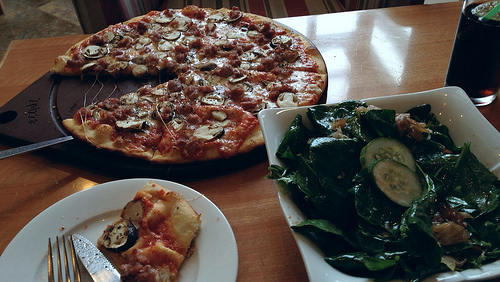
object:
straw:
[476, 1, 500, 23]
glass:
[442, 0, 499, 107]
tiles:
[1, 0, 36, 23]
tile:
[37, 0, 80, 25]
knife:
[69, 233, 124, 282]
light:
[278, 10, 413, 98]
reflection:
[270, 8, 417, 103]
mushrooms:
[114, 116, 148, 131]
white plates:
[39, 227, 119, 280]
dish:
[0, 177, 240, 281]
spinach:
[307, 139, 350, 182]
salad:
[321, 244, 405, 279]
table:
[288, 11, 410, 76]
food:
[102, 7, 404, 192]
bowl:
[255, 57, 499, 279]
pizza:
[97, 181, 202, 281]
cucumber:
[367, 157, 424, 209]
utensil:
[0, 133, 72, 158]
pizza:
[49, 4, 329, 163]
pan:
[49, 73, 172, 125]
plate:
[0, 176, 241, 282]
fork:
[45, 233, 85, 281]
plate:
[1, 7, 329, 177]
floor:
[1, 1, 83, 63]